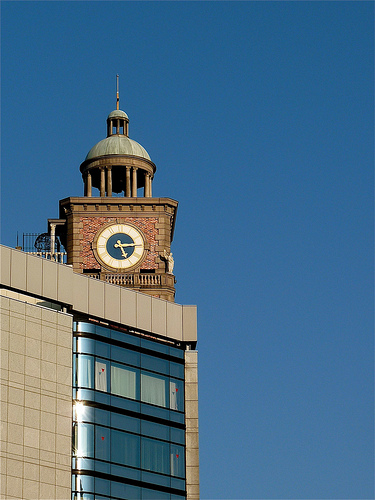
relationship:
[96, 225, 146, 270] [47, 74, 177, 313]
face on a tower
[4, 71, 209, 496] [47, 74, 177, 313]
building has tower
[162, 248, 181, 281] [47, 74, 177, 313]
statue on base of tower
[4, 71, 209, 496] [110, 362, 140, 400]
building has window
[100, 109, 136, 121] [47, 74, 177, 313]
dome on top of tower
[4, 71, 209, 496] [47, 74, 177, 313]
building with tower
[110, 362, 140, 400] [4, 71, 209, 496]
window on side of building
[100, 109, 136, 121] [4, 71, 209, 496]
dome near top of building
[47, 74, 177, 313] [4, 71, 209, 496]
tower on top of building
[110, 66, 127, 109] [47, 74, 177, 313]
pole on top of tower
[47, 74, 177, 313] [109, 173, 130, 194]
tower has bell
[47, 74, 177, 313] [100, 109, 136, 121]
tower with a dome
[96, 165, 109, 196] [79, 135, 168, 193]
pillar holding up dome